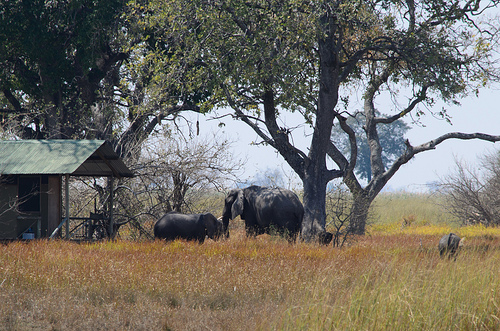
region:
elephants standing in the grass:
[39, 59, 440, 329]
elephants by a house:
[37, 90, 471, 330]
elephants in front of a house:
[47, 105, 485, 280]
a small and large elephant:
[148, 129, 493, 288]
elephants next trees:
[129, 62, 496, 277]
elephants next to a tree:
[125, 79, 410, 286]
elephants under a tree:
[58, 93, 469, 299]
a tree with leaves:
[129, 17, 458, 294]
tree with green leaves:
[143, 17, 442, 286]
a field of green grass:
[254, 265, 471, 320]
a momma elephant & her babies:
[146, 170, 473, 277]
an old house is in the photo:
[12, 119, 135, 256]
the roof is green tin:
[11, 120, 160, 200]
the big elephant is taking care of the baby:
[149, 183, 350, 258]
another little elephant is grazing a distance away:
[425, 217, 465, 274]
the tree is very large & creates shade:
[166, 8, 454, 185]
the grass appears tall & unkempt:
[21, 234, 421, 309]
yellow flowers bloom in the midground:
[378, 216, 498, 239]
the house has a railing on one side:
[49, 210, 120, 258]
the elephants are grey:
[141, 179, 311, 253]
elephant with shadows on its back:
[208, 163, 340, 257]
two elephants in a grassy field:
[145, 150, 334, 277]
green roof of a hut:
[7, 105, 132, 254]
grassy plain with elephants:
[2, 235, 448, 325]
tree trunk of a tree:
[297, 20, 337, 275]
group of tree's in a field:
[44, 1, 467, 201]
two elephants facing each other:
[150, 173, 319, 268]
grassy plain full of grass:
[10, 235, 437, 327]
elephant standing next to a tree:
[211, 72, 368, 254]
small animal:
[413, 212, 470, 281]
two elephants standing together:
[132, 177, 312, 252]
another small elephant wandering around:
[439, 227, 461, 259]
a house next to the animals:
[6, 135, 119, 243]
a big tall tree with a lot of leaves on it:
[128, 5, 494, 244]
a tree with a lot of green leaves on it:
[1, 0, 152, 148]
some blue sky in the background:
[221, 101, 496, 195]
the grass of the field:
[6, 235, 496, 327]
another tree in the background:
[330, 109, 415, 199]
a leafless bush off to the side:
[436, 156, 499, 223]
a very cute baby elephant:
[152, 210, 224, 242]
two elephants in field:
[157, 181, 335, 258]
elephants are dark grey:
[122, 173, 306, 249]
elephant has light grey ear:
[210, 181, 240, 220]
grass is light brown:
[42, 243, 344, 329]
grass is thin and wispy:
[19, 257, 386, 327]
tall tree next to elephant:
[245, 1, 443, 249]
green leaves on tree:
[129, 3, 375, 135]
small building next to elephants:
[0, 114, 111, 249]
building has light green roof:
[8, 148, 117, 169]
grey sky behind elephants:
[207, 136, 270, 186]